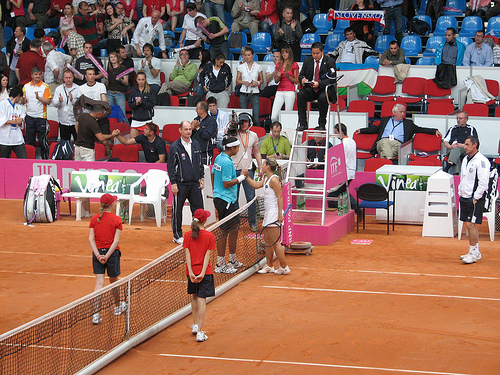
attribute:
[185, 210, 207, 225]
hat — red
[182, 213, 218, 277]
shirt — red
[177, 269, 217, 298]
shorts — black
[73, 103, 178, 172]
men — shaking hands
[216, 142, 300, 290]
women — shaking hands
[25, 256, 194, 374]
net — white, black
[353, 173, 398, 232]
chair — blue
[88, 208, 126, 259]
shirt — red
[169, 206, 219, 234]
hair — ponytail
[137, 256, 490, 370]
court — brown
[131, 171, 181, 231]
chair — plastic, white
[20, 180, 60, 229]
bag — black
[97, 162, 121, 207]
cap — red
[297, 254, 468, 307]
line — white